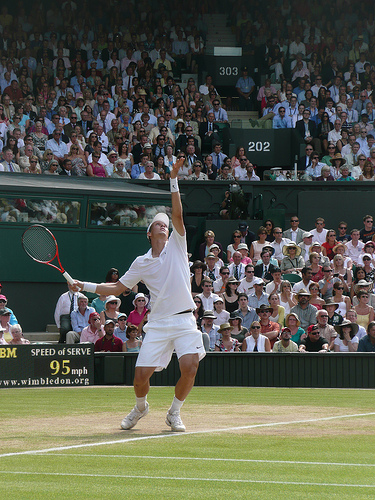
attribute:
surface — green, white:
[48, 445, 314, 499]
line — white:
[34, 417, 352, 438]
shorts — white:
[130, 309, 232, 377]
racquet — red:
[14, 210, 84, 292]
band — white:
[158, 169, 191, 200]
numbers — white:
[244, 130, 289, 165]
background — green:
[2, 169, 163, 239]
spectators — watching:
[7, 16, 236, 161]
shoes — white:
[115, 402, 218, 447]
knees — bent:
[113, 360, 239, 387]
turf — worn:
[22, 379, 315, 500]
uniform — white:
[93, 216, 226, 363]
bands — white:
[75, 277, 107, 302]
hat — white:
[139, 201, 175, 232]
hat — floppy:
[332, 312, 355, 330]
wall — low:
[97, 345, 359, 387]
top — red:
[323, 240, 342, 255]